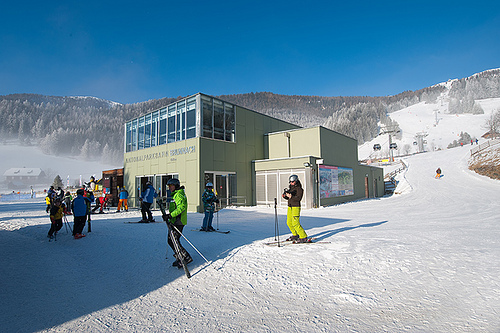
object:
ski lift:
[365, 126, 423, 159]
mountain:
[1, 67, 500, 183]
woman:
[270, 173, 309, 245]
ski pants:
[284, 204, 309, 238]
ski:
[264, 236, 313, 246]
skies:
[0, 4, 495, 100]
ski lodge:
[123, 92, 384, 208]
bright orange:
[434, 172, 443, 178]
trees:
[450, 67, 482, 114]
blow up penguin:
[85, 176, 103, 190]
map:
[318, 164, 357, 200]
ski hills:
[364, 96, 496, 213]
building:
[1, 167, 48, 188]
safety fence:
[471, 135, 496, 157]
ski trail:
[397, 135, 495, 206]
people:
[160, 178, 193, 268]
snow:
[10, 102, 496, 330]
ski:
[161, 203, 209, 279]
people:
[45, 193, 70, 241]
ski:
[46, 213, 76, 245]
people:
[132, 181, 161, 227]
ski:
[122, 216, 159, 225]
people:
[200, 183, 221, 232]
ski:
[200, 204, 232, 235]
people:
[70, 188, 94, 240]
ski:
[85, 200, 95, 233]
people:
[432, 167, 442, 181]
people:
[474, 138, 479, 146]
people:
[470, 140, 473, 147]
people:
[459, 142, 464, 148]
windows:
[223, 102, 235, 141]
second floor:
[123, 93, 360, 161]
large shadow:
[2, 209, 350, 332]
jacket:
[164, 186, 189, 230]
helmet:
[285, 174, 301, 183]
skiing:
[44, 174, 316, 276]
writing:
[123, 145, 201, 165]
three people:
[458, 137, 487, 146]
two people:
[166, 175, 231, 276]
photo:
[0, 2, 498, 331]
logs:
[5, 177, 40, 187]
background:
[3, 64, 498, 185]